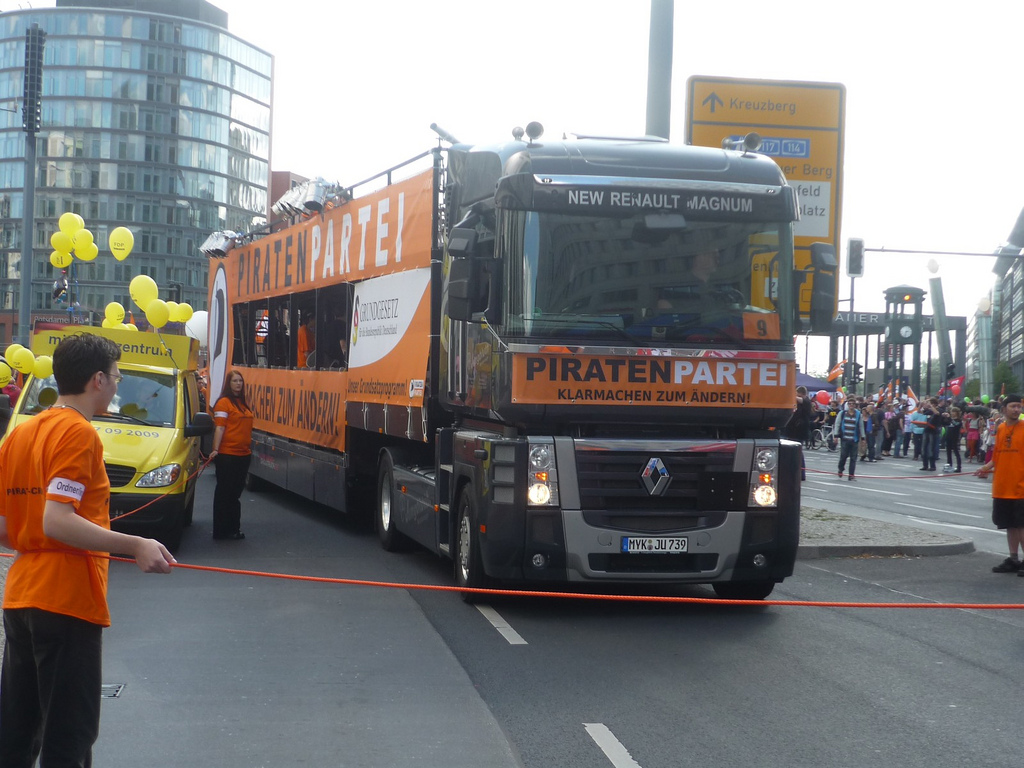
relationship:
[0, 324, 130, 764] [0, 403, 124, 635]
man in orange shirt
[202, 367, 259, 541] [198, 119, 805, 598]
woman standing by bus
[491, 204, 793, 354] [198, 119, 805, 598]
window of a bus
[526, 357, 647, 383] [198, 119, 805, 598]
pirate on bus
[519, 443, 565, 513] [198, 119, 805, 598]
headlight on bus